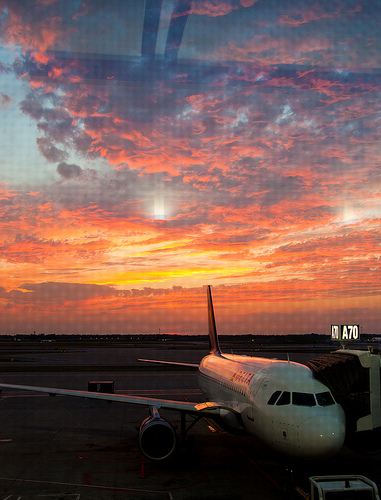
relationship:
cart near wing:
[86, 380, 119, 398] [23, 385, 219, 440]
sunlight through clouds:
[131, 164, 342, 243] [48, 65, 356, 198]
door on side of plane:
[247, 373, 269, 423] [17, 273, 375, 462]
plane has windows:
[17, 273, 375, 462] [269, 381, 335, 414]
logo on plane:
[220, 366, 263, 389] [17, 273, 375, 462]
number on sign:
[321, 316, 362, 351] [325, 309, 369, 353]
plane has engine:
[17, 273, 375, 462] [129, 420, 169, 467]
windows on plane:
[269, 381, 335, 414] [17, 273, 375, 462]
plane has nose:
[17, 273, 375, 462] [302, 420, 349, 455]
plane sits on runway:
[17, 273, 375, 462] [19, 334, 196, 398]